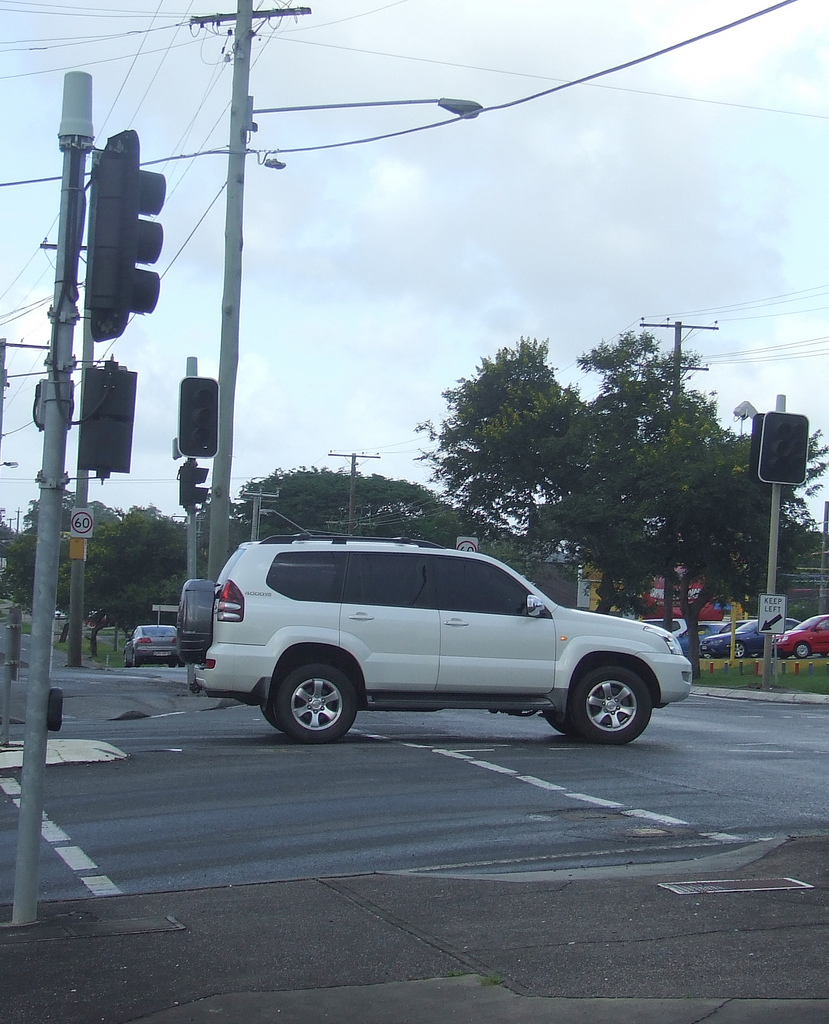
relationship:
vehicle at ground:
[164, 518, 702, 766] [0, 663, 829, 1024]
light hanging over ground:
[251, 98, 483, 118] [0, 663, 829, 1024]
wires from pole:
[2, 2, 799, 190] [207, 0, 255, 584]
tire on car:
[273, 662, 358, 745] [173, 537, 691, 748]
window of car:
[267, 551, 554, 620] [173, 537, 691, 748]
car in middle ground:
[173, 537, 691, 748] [0, 663, 829, 1024]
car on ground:
[176, 536, 693, 747] [0, 663, 829, 1024]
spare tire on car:
[168, 574, 213, 656] [176, 536, 693, 747]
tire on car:
[572, 660, 654, 744] [176, 536, 693, 747]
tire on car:
[271, 657, 356, 747] [176, 536, 693, 747]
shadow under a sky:
[335, 713, 561, 750] [286, 95, 718, 417]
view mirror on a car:
[508, 578, 560, 623] [176, 536, 693, 747]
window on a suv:
[277, 548, 521, 641] [166, 517, 728, 791]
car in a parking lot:
[760, 607, 827, 667] [633, 592, 827, 677]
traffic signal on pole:
[752, 404, 818, 498] [739, 381, 793, 605]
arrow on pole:
[752, 610, 791, 637] [748, 498, 818, 681]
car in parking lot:
[772, 614, 829, 660] [657, 584, 822, 704]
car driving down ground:
[121, 612, 200, 673] [0, 663, 829, 1024]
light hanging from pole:
[256, 85, 506, 143] [198, 15, 261, 593]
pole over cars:
[198, 15, 261, 593] [112, 535, 764, 822]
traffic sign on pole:
[57, 497, 105, 555] [56, 339, 138, 660]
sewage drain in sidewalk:
[651, 845, 827, 929] [504, 776, 816, 1017]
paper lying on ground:
[137, 731, 200, 773] [75, 669, 322, 861]